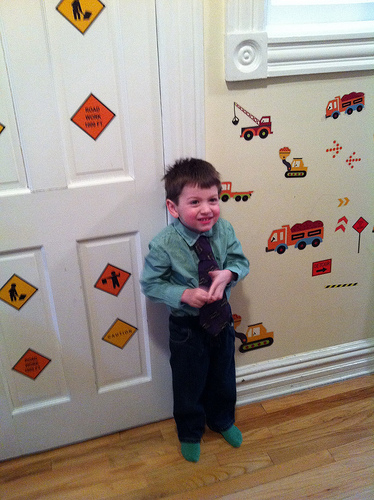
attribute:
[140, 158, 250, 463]
kid — dressed, playing, standing, little, shy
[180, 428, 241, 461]
socks — green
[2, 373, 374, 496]
floor — wooden, hardwood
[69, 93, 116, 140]
sticker — orange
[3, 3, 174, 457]
door — white, large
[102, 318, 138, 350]
sticker — yellow, caution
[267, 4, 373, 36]
window — blindless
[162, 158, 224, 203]
hair — short, brown, up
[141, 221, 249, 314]
shirt — green, dress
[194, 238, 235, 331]
tie — large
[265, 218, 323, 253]
sticker — tractor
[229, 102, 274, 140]
sticker — crane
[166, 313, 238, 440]
pants — dark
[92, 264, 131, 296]
sticker — person, construction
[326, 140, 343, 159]
arrow — dotted, red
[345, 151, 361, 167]
arrow — dotted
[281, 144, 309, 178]
sticker — trailer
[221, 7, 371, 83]
moulding — white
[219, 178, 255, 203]
sticker — truck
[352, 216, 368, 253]
sticker — red